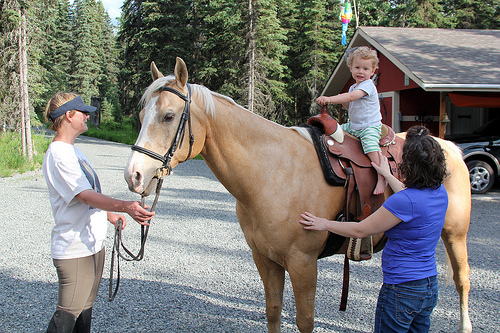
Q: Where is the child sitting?
A: A horse.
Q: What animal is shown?
A: A horse.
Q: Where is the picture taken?
A: A farm.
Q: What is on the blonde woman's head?
A: A visor.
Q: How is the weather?
A: Clear.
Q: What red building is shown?
A: A garage.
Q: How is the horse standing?
A: Still.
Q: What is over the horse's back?
A: A saddle.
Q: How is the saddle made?
A: Of leather.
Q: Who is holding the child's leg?
A: A woman.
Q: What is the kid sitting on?
A: A horse.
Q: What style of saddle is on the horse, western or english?
A: Western.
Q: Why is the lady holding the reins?
A: Keep horse still.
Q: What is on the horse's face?
A: A bridle.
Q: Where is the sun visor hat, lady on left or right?
A: Lady on left.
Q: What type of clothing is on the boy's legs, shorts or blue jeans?
A: Shorts.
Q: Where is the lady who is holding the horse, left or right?
A: Left.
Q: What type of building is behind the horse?
A: Stable.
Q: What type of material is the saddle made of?
A: Leather.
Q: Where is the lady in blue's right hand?
A: Boy's leg.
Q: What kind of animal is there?
A: A horse.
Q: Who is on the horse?
A: A kid.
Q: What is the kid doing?
A: Sitting on a horse.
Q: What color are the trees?
A: Green.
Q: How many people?
A: 3.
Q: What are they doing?
A: Riding a horse.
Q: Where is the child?
A: On the saddle.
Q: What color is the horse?
A: Brown.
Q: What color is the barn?
A: Red.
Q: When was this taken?
A: Daytime.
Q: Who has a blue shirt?
A: The woman on the right.